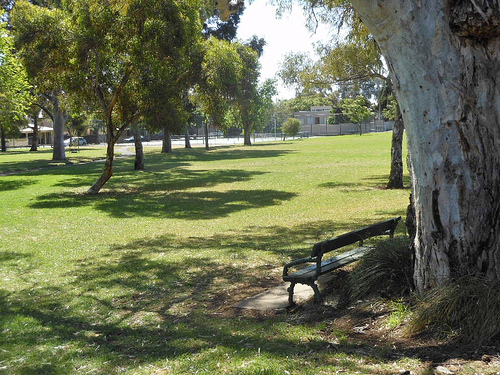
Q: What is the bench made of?
A: Wrought Iron.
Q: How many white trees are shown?
A: One.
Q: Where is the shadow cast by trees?
A: On the ground.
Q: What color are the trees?
A: Green.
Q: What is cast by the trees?
A: Shadows.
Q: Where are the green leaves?
A: On the tree.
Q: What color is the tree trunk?
A: Brown.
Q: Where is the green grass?
A: On the ground.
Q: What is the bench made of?
A: Wood.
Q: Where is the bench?
A: Near a tree.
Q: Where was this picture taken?
A: A park.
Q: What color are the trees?
A: Green.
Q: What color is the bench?
A: Brown.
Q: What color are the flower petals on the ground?
A: White.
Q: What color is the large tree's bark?
A: Grey.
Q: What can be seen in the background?
A: A building.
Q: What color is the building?
A: White.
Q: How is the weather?
A: Clear.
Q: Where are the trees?
A: In the park.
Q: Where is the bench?
A: In front of tree.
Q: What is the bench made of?
A: Wood.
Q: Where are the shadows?
A: On the ground.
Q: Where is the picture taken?
A: In the park.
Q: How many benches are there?
A: One.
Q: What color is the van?
A: White.